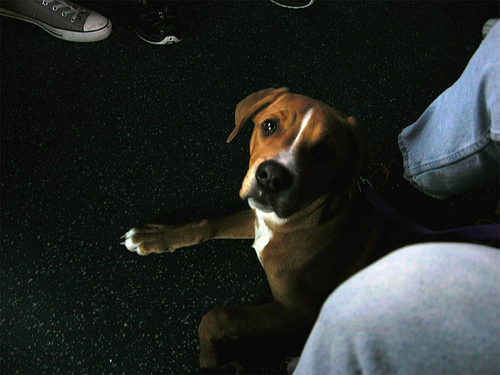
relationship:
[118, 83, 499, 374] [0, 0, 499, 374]
dog lying on ground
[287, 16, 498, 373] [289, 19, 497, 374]
man wearing jeans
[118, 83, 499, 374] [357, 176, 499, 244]
dog tied on a leash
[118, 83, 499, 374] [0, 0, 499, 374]
dog on top of ground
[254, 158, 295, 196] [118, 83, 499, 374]
nose of a dog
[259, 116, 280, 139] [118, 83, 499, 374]
eye of a dog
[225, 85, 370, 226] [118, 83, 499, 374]
head of a dog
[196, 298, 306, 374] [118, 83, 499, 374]
front leg of a dog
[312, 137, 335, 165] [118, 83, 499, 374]
left eye of a dog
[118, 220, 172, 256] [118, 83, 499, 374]
paw of a dog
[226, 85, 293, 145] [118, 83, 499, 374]
ear of a dog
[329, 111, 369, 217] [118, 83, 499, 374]
left ear of a dog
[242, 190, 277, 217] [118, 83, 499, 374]
mouth of a dog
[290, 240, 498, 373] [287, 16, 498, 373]
knee of a man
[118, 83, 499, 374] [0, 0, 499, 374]
dog laying on ground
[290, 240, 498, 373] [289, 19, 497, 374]
knee dressed in jeans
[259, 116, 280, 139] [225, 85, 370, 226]
eye on front of head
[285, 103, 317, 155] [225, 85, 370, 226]
marking on front of head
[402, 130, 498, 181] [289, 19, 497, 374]
seam sewn on jeans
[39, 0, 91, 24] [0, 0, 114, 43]
lace on top of shoe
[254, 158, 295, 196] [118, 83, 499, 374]
nose on front of dog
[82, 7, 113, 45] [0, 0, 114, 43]
tip of shoe